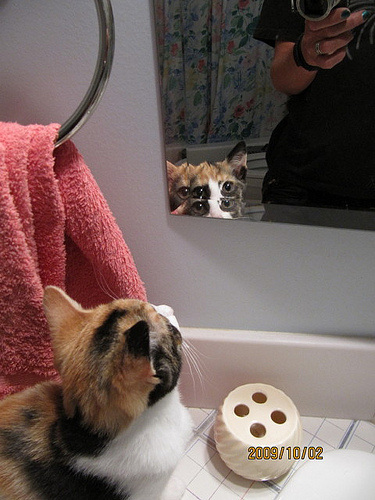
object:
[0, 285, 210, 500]
cat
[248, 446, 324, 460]
date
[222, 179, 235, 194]
eye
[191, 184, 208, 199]
eye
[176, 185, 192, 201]
eye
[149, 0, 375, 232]
mirror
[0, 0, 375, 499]
bathroom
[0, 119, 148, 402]
towel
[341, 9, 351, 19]
nail polish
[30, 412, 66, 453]
fur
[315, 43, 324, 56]
ring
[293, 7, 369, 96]
hand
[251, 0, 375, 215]
person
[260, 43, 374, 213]
black shirt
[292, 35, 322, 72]
watch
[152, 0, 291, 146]
shower curtain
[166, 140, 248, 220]
cat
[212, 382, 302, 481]
holder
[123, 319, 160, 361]
ear